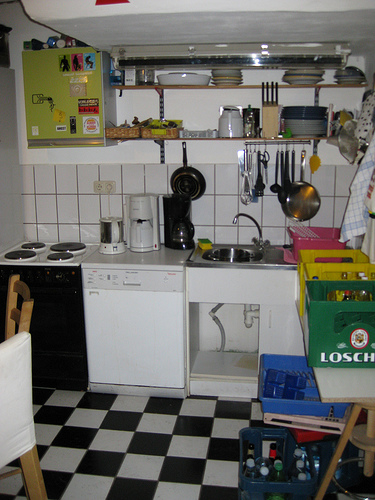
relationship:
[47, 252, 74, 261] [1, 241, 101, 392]
burner on stove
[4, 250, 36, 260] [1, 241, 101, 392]
burner on stove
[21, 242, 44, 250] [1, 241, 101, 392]
burner on stove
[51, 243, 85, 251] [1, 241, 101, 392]
burner on stove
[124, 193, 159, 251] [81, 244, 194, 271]
coffee pot on counter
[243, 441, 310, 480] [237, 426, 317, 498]
bottles in crate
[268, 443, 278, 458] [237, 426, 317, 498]
bottle in crate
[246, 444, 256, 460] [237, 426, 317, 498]
bottle in crate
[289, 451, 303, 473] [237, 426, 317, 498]
bottle in crate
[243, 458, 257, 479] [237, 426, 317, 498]
bottle in crate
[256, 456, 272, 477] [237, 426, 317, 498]
bottle in crate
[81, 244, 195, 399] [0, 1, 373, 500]
dishwasher in kitchen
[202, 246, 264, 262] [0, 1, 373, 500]
sink in kitchen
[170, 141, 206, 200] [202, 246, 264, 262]
frying pan above sink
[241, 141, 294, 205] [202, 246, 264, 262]
utensils hanging above sink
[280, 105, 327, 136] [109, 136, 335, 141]
plates on shelf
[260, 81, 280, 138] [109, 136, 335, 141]
knife set on shelf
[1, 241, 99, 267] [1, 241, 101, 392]
top of stove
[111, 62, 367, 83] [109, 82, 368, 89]
dishware on shelf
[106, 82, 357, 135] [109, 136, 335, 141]
dishware on shelf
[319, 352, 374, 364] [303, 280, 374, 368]
losch on crate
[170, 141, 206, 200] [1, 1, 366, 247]
frying pan hanging on wall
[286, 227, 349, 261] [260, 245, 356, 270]
dish rack on counter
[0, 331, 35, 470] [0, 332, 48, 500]
back of chair